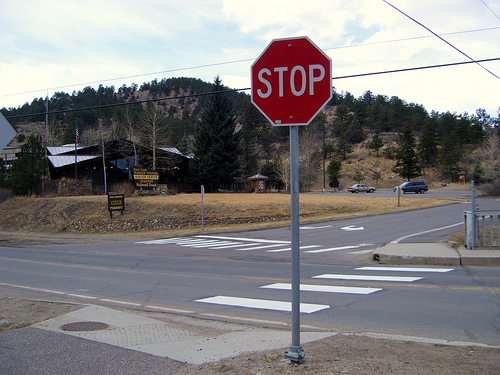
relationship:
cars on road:
[348, 181, 429, 197] [222, 203, 468, 276]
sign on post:
[245, 36, 334, 129] [286, 130, 308, 364]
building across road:
[46, 137, 194, 191] [222, 203, 468, 276]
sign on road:
[245, 36, 334, 129] [222, 203, 468, 276]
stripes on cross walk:
[190, 290, 325, 323] [197, 259, 436, 324]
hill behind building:
[117, 73, 228, 145] [46, 137, 194, 191]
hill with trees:
[117, 73, 228, 145] [70, 85, 133, 122]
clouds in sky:
[7, 3, 222, 66] [5, 3, 499, 103]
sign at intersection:
[245, 36, 334, 129] [63, 229, 381, 328]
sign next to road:
[245, 36, 334, 129] [222, 203, 468, 276]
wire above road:
[349, 57, 480, 80] [222, 203, 468, 276]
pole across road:
[320, 123, 329, 190] [222, 203, 468, 276]